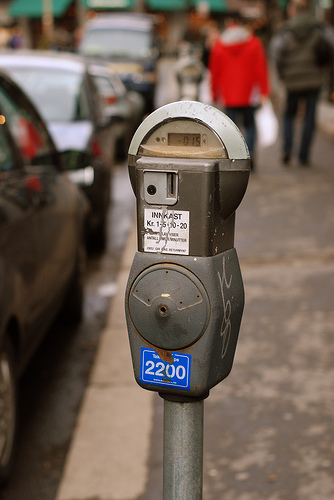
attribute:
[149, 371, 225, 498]
post — here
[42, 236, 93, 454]
road — here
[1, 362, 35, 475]
rim — here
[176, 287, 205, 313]
line — here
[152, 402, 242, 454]
metal — here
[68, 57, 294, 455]
parking meter — here, grey, gray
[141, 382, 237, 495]
pole — metal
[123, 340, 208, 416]
sticker — blue, rectangular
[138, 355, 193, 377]
number — white, here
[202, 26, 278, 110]
jacket — red, orange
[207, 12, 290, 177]
person — walking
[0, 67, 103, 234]
car — parked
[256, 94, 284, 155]
bag — here, white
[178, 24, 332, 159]
pedestrians — walking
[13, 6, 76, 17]
awning — green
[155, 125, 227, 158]
screen — digital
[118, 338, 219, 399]
sign — blue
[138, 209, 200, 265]
sign — white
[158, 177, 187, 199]
coin slot — metal, black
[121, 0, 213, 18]
patio cover — green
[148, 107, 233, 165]
sign — digital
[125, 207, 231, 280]
sticker — white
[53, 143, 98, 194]
mirror — here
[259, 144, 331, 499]
walkpath — here